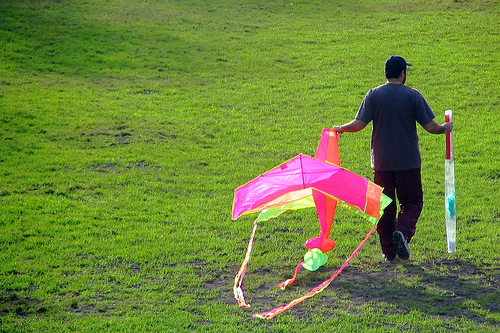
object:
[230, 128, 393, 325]
kite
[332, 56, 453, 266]
man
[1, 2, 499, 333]
grass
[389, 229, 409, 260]
sneaker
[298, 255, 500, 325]
shadow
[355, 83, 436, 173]
t-shirt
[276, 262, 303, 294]
tassel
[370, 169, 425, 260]
pants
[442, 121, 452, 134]
hand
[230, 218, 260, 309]
tail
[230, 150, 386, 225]
wing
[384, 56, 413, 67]
cap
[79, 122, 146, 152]
part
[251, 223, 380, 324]
ribbon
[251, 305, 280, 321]
part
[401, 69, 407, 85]
beard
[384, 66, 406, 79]
hair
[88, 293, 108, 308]
patch